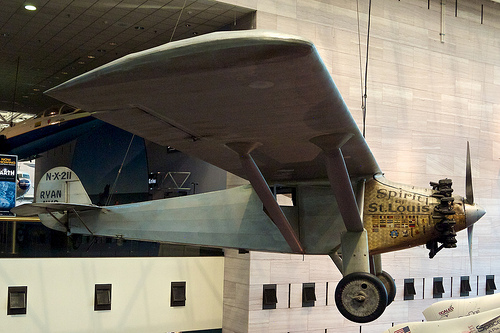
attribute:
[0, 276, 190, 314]
windows — little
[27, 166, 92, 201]
fin — round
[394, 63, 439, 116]
tiles — white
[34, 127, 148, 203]
wall — blue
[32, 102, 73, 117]
cockpit — glass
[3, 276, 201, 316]
squares — black 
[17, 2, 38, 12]
light — recessed 